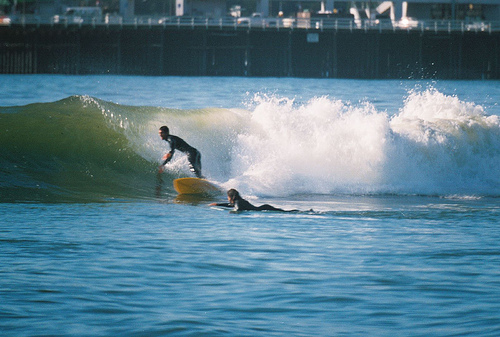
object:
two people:
[159, 125, 316, 213]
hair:
[227, 189, 241, 201]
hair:
[159, 126, 169, 135]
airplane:
[21, 10, 90, 25]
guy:
[158, 125, 206, 179]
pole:
[175, 177, 223, 195]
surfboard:
[173, 177, 223, 193]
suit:
[163, 134, 206, 179]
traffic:
[158, 6, 280, 26]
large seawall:
[2, 97, 353, 202]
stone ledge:
[326, 87, 500, 196]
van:
[237, 13, 281, 28]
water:
[0, 75, 500, 337]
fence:
[276, 18, 384, 33]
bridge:
[0, 14, 499, 80]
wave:
[0, 88, 499, 203]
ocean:
[19, 211, 491, 333]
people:
[209, 188, 316, 214]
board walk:
[1, 19, 500, 80]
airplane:
[348, 1, 422, 30]